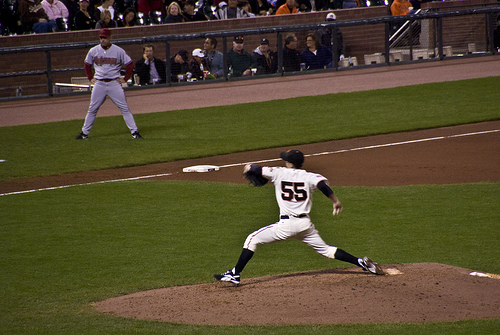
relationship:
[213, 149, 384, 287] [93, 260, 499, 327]
pitcher on mound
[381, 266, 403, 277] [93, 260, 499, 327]
rubber on mound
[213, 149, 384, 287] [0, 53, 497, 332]
pitcher on field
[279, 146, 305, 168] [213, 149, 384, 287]
hat on pitcher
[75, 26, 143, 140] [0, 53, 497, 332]
coach on field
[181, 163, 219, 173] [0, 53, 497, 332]
base on field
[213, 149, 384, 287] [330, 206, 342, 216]
pitcher has ball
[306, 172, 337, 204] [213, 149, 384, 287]
arm of pitcher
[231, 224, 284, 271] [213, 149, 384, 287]
leg of pitcher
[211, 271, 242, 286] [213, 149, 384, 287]
cleat of pitcher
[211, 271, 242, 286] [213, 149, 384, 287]
cleat on pitcher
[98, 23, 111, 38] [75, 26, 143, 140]
cap on coach